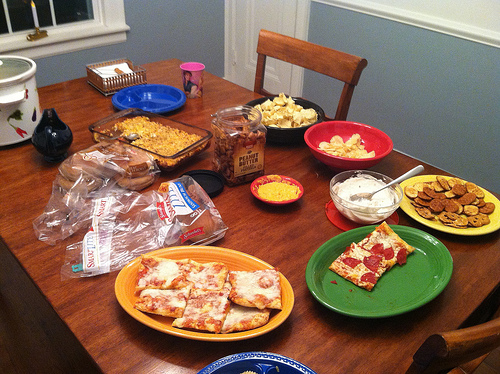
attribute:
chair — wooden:
[248, 28, 357, 124]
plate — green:
[311, 222, 447, 319]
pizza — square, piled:
[335, 226, 410, 286]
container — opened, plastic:
[210, 110, 269, 186]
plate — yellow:
[399, 170, 499, 240]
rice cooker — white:
[2, 55, 42, 147]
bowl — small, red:
[247, 171, 304, 205]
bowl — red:
[311, 116, 390, 174]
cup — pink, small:
[179, 62, 209, 101]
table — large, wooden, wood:
[11, 61, 490, 374]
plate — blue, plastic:
[114, 82, 184, 113]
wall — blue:
[313, 5, 499, 163]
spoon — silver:
[351, 163, 425, 201]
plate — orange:
[110, 245, 296, 338]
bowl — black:
[245, 93, 325, 142]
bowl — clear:
[332, 169, 402, 221]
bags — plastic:
[45, 138, 222, 269]